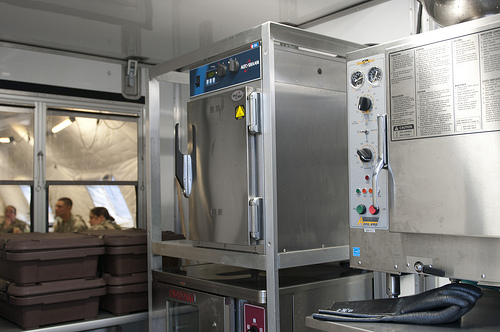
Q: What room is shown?
A: It is a kitchen.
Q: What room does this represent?
A: It represents the kitchen.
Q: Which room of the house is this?
A: It is a kitchen.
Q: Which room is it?
A: It is a kitchen.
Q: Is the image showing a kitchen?
A: Yes, it is showing a kitchen.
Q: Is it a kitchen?
A: Yes, it is a kitchen.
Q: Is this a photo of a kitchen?
A: Yes, it is showing a kitchen.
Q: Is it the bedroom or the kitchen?
A: It is the kitchen.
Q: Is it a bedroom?
A: No, it is a kitchen.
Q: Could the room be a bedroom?
A: No, it is a kitchen.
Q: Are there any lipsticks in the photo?
A: No, there are no lipsticks.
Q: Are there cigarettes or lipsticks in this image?
A: No, there are no lipsticks or cigarettes.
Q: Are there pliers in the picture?
A: No, there are no pliers.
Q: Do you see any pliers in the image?
A: No, there are no pliers.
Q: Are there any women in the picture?
A: Yes, there is a woman.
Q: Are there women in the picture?
A: Yes, there is a woman.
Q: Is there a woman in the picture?
A: Yes, there is a woman.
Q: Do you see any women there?
A: Yes, there is a woman.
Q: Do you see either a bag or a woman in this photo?
A: Yes, there is a woman.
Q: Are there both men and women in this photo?
A: Yes, there are both a woman and a man.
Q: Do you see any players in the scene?
A: No, there are no players.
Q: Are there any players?
A: No, there are no players.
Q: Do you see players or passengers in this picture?
A: No, there are no players or passengers.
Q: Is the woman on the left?
A: Yes, the woman is on the left of the image.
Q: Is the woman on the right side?
A: No, the woman is on the left of the image.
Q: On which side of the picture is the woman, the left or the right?
A: The woman is on the left of the image.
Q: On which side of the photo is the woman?
A: The woman is on the left of the image.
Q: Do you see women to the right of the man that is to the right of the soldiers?
A: Yes, there is a woman to the right of the man.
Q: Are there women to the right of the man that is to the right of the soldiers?
A: Yes, there is a woman to the right of the man.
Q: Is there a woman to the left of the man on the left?
A: No, the woman is to the right of the man.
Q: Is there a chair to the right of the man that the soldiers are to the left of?
A: No, there is a woman to the right of the man.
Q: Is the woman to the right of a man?
A: Yes, the woman is to the right of a man.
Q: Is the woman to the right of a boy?
A: No, the woman is to the right of a man.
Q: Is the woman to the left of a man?
A: No, the woman is to the right of a man.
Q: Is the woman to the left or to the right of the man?
A: The woman is to the right of the man.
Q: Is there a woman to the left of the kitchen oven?
A: Yes, there is a woman to the left of the oven.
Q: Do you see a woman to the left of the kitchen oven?
A: Yes, there is a woman to the left of the oven.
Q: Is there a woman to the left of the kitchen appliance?
A: Yes, there is a woman to the left of the oven.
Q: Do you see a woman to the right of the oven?
A: No, the woman is to the left of the oven.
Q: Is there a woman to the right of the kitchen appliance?
A: No, the woman is to the left of the oven.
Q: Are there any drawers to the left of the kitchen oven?
A: No, there is a woman to the left of the oven.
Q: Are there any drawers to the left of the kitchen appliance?
A: No, there is a woman to the left of the oven.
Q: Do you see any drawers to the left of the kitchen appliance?
A: No, there is a woman to the left of the oven.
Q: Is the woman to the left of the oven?
A: Yes, the woman is to the left of the oven.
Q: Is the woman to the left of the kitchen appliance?
A: Yes, the woman is to the left of the oven.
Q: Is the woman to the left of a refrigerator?
A: No, the woman is to the left of the oven.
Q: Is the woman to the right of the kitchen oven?
A: No, the woman is to the left of the oven.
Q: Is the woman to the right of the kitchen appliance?
A: No, the woman is to the left of the oven.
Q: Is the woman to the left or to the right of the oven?
A: The woman is to the left of the oven.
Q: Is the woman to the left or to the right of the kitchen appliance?
A: The woman is to the left of the oven.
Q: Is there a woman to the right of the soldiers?
A: Yes, there is a woman to the right of the soldiers.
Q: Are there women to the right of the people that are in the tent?
A: Yes, there is a woman to the right of the soldiers.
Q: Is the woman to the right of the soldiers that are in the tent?
A: Yes, the woman is to the right of the soldiers.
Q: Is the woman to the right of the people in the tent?
A: Yes, the woman is to the right of the soldiers.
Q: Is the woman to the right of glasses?
A: No, the woman is to the right of the soldiers.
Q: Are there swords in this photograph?
A: No, there are no swords.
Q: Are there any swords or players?
A: No, there are no swords or players.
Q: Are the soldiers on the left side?
A: Yes, the soldiers are on the left of the image.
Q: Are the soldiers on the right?
A: No, the soldiers are on the left of the image.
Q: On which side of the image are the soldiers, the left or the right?
A: The soldiers are on the left of the image.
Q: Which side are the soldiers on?
A: The soldiers are on the left of the image.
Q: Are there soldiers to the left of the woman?
A: Yes, there are soldiers to the left of the woman.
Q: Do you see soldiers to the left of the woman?
A: Yes, there are soldiers to the left of the woman.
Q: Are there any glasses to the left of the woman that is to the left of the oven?
A: No, there are soldiers to the left of the woman.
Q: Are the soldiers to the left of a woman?
A: Yes, the soldiers are to the left of a woman.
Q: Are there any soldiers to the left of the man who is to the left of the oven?
A: Yes, there are soldiers to the left of the man.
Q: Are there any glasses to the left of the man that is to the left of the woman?
A: No, there are soldiers to the left of the man.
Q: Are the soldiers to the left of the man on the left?
A: Yes, the soldiers are to the left of the man.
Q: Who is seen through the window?
A: The soldiers are seen through the window.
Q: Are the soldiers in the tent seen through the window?
A: Yes, the soldiers are seen through the window.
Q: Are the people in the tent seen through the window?
A: Yes, the soldiers are seen through the window.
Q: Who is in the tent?
A: The soldiers are in the tent.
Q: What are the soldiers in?
A: The soldiers are in the tent.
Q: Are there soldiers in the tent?
A: Yes, there are soldiers in the tent.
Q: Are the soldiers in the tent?
A: Yes, the soldiers are in the tent.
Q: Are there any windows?
A: Yes, there is a window.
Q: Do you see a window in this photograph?
A: Yes, there is a window.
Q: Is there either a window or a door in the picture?
A: Yes, there is a window.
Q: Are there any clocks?
A: No, there are no clocks.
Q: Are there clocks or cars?
A: No, there are no clocks or cars.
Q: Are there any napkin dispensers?
A: No, there are no napkin dispensers.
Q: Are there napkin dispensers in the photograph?
A: No, there are no napkin dispensers.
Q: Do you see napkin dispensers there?
A: No, there are no napkin dispensers.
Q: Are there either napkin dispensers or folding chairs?
A: No, there are no napkin dispensers or folding chairs.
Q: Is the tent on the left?
A: Yes, the tent is on the left of the image.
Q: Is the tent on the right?
A: No, the tent is on the left of the image.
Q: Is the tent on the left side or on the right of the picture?
A: The tent is on the left of the image.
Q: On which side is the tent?
A: The tent is on the left of the image.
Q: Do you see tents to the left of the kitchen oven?
A: Yes, there is a tent to the left of the oven.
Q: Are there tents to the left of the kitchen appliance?
A: Yes, there is a tent to the left of the oven.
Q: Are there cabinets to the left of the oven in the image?
A: No, there is a tent to the left of the oven.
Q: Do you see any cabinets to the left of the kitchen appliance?
A: No, there is a tent to the left of the oven.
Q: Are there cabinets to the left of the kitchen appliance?
A: No, there is a tent to the left of the oven.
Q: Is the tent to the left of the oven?
A: Yes, the tent is to the left of the oven.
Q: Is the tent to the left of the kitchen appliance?
A: Yes, the tent is to the left of the oven.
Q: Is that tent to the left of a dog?
A: No, the tent is to the left of the oven.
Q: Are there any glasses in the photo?
A: No, there are no glasses.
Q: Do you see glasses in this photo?
A: No, there are no glasses.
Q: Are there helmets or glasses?
A: No, there are no glasses or helmets.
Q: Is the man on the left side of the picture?
A: Yes, the man is on the left of the image.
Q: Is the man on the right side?
A: No, the man is on the left of the image.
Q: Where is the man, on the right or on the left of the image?
A: The man is on the left of the image.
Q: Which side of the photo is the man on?
A: The man is on the left of the image.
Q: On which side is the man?
A: The man is on the left of the image.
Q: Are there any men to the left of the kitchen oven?
A: Yes, there is a man to the left of the oven.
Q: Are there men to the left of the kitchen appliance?
A: Yes, there is a man to the left of the oven.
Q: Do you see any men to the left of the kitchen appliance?
A: Yes, there is a man to the left of the oven.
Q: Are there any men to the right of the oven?
A: No, the man is to the left of the oven.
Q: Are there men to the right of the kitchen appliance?
A: No, the man is to the left of the oven.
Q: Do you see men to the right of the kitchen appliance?
A: No, the man is to the left of the oven.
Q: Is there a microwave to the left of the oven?
A: No, there is a man to the left of the oven.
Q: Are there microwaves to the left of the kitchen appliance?
A: No, there is a man to the left of the oven.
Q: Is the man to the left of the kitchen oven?
A: Yes, the man is to the left of the oven.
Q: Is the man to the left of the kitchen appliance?
A: Yes, the man is to the left of the oven.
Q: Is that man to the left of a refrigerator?
A: No, the man is to the left of the oven.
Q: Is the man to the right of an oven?
A: No, the man is to the left of an oven.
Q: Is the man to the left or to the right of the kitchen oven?
A: The man is to the left of the oven.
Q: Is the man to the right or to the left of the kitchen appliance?
A: The man is to the left of the oven.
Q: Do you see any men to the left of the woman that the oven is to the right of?
A: Yes, there is a man to the left of the woman.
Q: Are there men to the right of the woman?
A: No, the man is to the left of the woman.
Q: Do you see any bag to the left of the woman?
A: No, there is a man to the left of the woman.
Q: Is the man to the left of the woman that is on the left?
A: Yes, the man is to the left of the woman.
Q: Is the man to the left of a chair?
A: No, the man is to the left of the woman.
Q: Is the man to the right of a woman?
A: No, the man is to the left of a woman.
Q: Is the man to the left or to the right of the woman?
A: The man is to the left of the woman.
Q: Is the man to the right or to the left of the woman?
A: The man is to the left of the woman.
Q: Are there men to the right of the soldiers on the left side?
A: Yes, there is a man to the right of the soldiers.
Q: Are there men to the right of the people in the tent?
A: Yes, there is a man to the right of the soldiers.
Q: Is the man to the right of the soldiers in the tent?
A: Yes, the man is to the right of the soldiers.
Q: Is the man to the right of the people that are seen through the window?
A: Yes, the man is to the right of the soldiers.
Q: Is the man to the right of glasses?
A: No, the man is to the right of the soldiers.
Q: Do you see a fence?
A: No, there are no fences.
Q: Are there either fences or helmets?
A: No, there are no fences or helmets.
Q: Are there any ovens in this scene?
A: Yes, there is an oven.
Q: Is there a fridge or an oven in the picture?
A: Yes, there is an oven.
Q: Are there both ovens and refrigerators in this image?
A: No, there is an oven but no refrigerators.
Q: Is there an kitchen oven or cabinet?
A: Yes, there is a kitchen oven.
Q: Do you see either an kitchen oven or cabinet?
A: Yes, there is a kitchen oven.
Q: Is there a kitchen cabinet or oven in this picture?
A: Yes, there is a kitchen oven.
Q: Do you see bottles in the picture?
A: No, there are no bottles.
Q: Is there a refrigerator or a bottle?
A: No, there are no bottles or refrigerators.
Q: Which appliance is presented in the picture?
A: The appliance is an oven.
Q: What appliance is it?
A: The appliance is an oven.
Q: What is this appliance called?
A: This is an oven.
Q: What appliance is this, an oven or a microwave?
A: This is an oven.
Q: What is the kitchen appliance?
A: The appliance is an oven.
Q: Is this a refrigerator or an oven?
A: This is an oven.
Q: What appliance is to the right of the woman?
A: The appliance is an oven.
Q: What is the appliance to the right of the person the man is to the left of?
A: The appliance is an oven.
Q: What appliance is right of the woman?
A: The appliance is an oven.